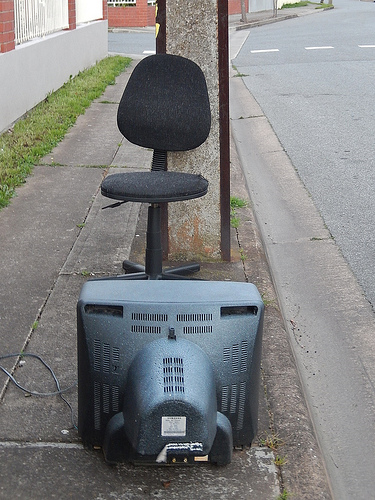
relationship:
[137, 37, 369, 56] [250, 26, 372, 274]
area on street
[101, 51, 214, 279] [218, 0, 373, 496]
chair next to road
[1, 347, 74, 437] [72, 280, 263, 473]
cord connected to tv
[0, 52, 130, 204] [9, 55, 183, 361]
grass next to sidewalk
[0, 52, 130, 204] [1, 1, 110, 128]
grass next to building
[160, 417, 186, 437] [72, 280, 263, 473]
tag stuck to tv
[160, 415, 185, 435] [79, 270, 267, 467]
lable stuck to television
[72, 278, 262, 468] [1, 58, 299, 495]
television sitting on sidewalk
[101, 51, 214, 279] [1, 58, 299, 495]
chair on sidewalk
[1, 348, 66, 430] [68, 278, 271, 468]
power cord on television set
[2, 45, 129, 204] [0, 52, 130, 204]
median on grass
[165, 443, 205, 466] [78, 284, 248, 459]
cable jacks on television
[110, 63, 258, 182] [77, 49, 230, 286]
cushion of an office chair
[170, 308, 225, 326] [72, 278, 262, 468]
vent on television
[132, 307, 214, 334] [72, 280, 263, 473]
holes on tv